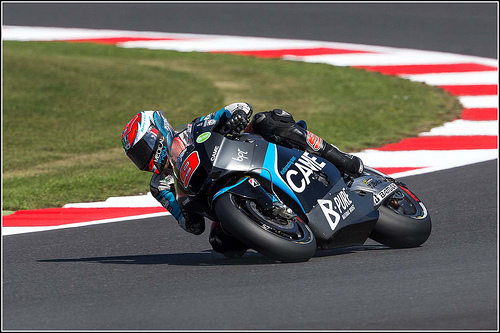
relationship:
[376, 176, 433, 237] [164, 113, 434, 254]
strut on side of bike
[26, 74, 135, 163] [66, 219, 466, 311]
grass on racetrack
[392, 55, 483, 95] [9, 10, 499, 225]
line on curve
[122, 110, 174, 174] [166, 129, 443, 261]
helmet on bike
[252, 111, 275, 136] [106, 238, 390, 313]
knee on track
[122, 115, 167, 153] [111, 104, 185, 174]
helmet on head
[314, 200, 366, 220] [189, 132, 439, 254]
writing on bottom of bike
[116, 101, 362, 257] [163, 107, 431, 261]
man leaning on motorbike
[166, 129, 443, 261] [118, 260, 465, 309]
bike turning on racetrack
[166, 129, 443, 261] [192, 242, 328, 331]
bike turning on track